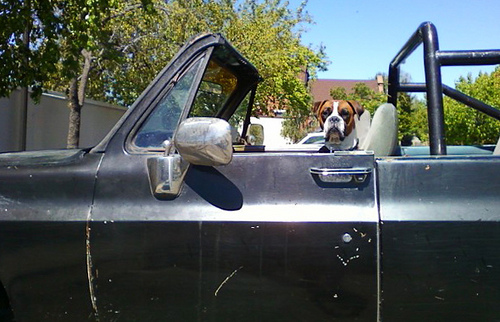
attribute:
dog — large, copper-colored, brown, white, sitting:
[315, 100, 363, 147]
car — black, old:
[11, 16, 497, 318]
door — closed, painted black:
[103, 33, 377, 317]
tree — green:
[0, 5, 141, 150]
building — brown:
[262, 82, 385, 137]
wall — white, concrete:
[3, 82, 129, 157]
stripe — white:
[324, 101, 344, 135]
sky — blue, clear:
[234, 2, 495, 73]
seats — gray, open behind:
[354, 103, 398, 157]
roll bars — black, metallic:
[377, 19, 499, 158]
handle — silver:
[309, 163, 373, 178]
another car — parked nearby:
[291, 131, 323, 145]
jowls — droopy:
[324, 126, 342, 141]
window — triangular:
[125, 46, 210, 146]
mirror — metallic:
[145, 119, 247, 199]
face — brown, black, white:
[310, 99, 367, 141]